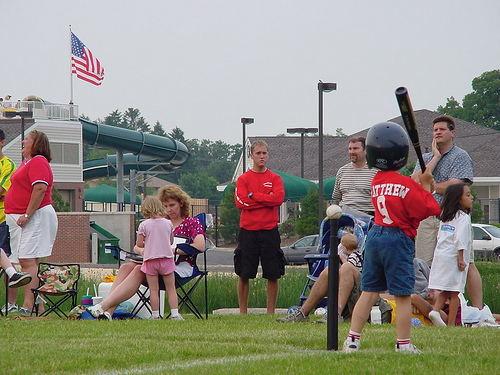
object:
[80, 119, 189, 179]
water slide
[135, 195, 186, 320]
girl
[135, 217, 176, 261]
shirt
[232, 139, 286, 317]
boy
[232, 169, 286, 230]
shirt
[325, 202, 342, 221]
baseball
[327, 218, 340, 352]
t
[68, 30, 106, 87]
flag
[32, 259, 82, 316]
chair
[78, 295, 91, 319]
cup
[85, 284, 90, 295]
straw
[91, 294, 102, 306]
cup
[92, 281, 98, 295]
straw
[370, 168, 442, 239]
shirt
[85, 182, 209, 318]
mother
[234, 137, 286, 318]
man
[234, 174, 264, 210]
arms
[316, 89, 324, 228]
pole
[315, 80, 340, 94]
street light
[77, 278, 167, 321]
water cooler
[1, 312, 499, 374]
grass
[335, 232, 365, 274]
baby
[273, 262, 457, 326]
father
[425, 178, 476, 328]
girl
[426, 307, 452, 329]
socks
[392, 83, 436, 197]
bat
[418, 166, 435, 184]
hand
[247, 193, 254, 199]
hands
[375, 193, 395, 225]
9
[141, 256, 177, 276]
shorts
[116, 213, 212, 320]
chair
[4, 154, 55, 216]
shirt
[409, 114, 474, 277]
man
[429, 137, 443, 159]
hand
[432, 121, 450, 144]
face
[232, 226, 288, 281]
shorts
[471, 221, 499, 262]
car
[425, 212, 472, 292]
tee shirt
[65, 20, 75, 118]
pole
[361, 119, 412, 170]
helmet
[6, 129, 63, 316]
woman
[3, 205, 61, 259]
shorts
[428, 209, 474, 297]
shirt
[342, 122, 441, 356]
boy